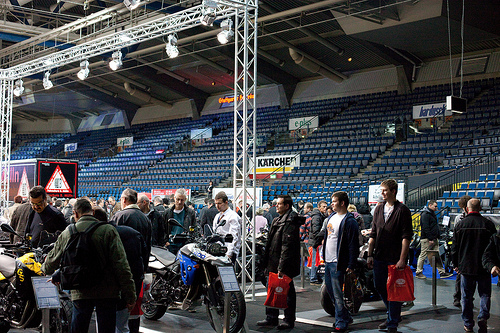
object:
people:
[2, 183, 71, 318]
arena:
[2, 0, 499, 206]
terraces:
[21, 145, 34, 155]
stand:
[265, 175, 387, 211]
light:
[162, 41, 185, 59]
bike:
[147, 226, 251, 332]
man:
[366, 174, 419, 331]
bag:
[383, 265, 415, 306]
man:
[315, 189, 363, 332]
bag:
[336, 263, 370, 316]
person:
[42, 199, 139, 332]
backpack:
[57, 236, 107, 293]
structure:
[1, 3, 259, 205]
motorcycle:
[2, 218, 66, 332]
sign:
[31, 276, 66, 311]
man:
[257, 191, 305, 331]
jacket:
[262, 211, 308, 279]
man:
[204, 191, 247, 265]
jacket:
[206, 208, 247, 256]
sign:
[246, 151, 303, 182]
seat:
[485, 190, 500, 207]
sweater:
[324, 212, 362, 274]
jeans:
[320, 264, 352, 328]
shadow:
[360, 302, 457, 328]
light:
[40, 74, 57, 92]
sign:
[37, 158, 82, 201]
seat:
[488, 172, 497, 180]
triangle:
[44, 163, 73, 195]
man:
[416, 196, 452, 282]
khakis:
[413, 236, 447, 273]